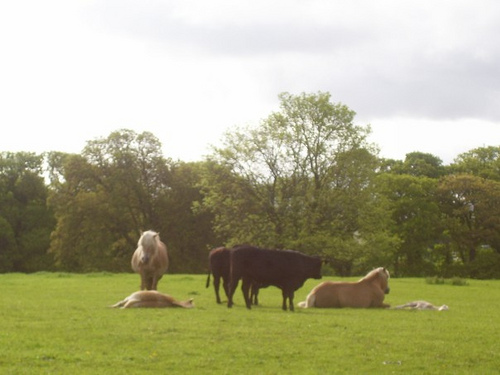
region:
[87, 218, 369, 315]
horses and cows in field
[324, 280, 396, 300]
the horse is laying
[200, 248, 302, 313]
the cows are standing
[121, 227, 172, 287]
the horse is standing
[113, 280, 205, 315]
the horse is laying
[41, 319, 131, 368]
the grass is short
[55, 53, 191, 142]
the sky is bright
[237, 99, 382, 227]
the trees are tall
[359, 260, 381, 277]
mane of the horse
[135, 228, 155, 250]
mane of the horse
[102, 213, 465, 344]
THESE ANIMALS ARE IN THE FIELD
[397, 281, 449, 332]
THIS HORSE IS LYING ON IT'S SIDE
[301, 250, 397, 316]
THIS HORSE IS RESTING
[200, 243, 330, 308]
THESE COWS ARE BLACK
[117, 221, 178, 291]
THIS HORSE IS STANDING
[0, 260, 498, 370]
THE FIELD IS LUSH AND GRASSY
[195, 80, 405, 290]
THIS TREE IS VERY LARGE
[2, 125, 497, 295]
THE TREES LINE THE EDGE OF THE FIELD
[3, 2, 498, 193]
THE SUMMER SKY IS VERY BRIGHT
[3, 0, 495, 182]
THE SKY IS FILLED WITH CLOUDS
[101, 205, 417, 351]
small ponies on grass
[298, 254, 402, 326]
the horse is resting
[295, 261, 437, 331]
the horse is resting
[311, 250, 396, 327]
the horse is resting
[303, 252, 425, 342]
the horse is resting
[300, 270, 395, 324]
the horse is resting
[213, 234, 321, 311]
the cow is black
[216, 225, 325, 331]
the cow is black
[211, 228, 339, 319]
the cow is black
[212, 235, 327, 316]
the cow is black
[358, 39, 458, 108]
a white cloud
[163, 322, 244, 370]
the green grass on the field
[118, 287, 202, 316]
an animal laying on the grass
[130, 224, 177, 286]
a horse standing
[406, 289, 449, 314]
an animal laying down